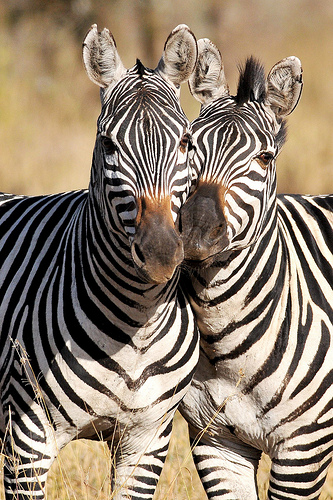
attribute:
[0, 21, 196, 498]
zebra — stripped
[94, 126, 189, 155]
eyes — brown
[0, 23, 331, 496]
zebras — standing, stripped, together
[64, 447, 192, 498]
grass — tan, dry, dead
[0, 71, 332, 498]
stripes — white, black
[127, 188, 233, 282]
noses — black, colored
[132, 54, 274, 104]
zebras mane — furry, black